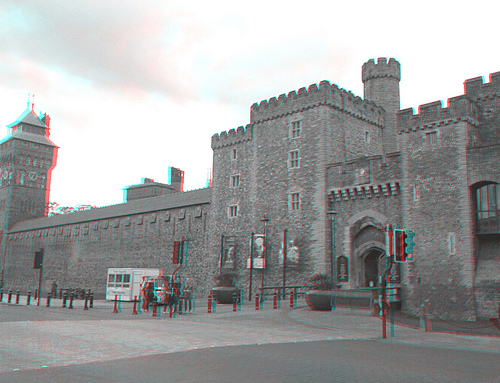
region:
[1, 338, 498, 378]
Dark gray ground surface in the foreground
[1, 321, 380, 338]
Multi-colored ground surface behind the dark gray in the foreground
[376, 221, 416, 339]
First signal displaying a red light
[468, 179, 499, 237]
Barred window on the far right of the building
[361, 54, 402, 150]
Round pillar at the top of the building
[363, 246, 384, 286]
Arched entry door to the building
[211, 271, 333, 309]
Two large pots with bushes in them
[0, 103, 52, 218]
Square tower with a pointed top on the far left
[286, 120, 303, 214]
Vertical row of three windows closest to us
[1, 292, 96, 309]
Row of short poles in the ground on the left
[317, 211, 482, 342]
Light by the building.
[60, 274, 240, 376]
Poles by the building.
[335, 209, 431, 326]
Door of the building.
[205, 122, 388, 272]
Windows on the building.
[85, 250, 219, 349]
Vehicle by the building.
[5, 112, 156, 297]
A tower portion of the building.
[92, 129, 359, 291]
Sky behind the building.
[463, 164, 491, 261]
Window on the bricks.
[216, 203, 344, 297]
Decorations on the wall.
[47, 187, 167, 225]
Trees against the sky.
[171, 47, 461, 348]
Old building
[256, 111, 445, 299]
An old castle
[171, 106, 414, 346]
An old prison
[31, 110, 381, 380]
3D generated photo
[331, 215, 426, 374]
Entrance to building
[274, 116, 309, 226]
Windows on the building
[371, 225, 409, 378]
Traffic light along road way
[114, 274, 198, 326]
People walking in front of the building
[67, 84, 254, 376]
Brick walkway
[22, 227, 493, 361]
Traffic lights at an intersection in front of the castle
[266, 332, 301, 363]
part of a road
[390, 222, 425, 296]
part of a traffic light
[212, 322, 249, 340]
part of a walking path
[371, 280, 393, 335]
part of a post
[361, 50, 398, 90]
tip of a castle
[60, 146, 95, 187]
part of the sky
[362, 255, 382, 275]
section of the entrance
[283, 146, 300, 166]
a window on the castle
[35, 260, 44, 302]
part of a black post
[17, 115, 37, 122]
part of a roof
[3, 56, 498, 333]
Gray historical building.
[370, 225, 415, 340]
Traffic light on a black and red pole.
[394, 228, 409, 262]
Black traffic light on red and black pole.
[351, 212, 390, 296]
Entrance doorway to historical building.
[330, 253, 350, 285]
Sign on the building beside the entrance doorway.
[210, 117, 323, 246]
Six windows on the front walls of building.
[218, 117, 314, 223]
Windows on the exterior walls.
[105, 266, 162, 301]
White small building in front of historical building.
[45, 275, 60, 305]
Person walking side the building.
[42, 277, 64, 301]
Man walking on side of street beside the building.